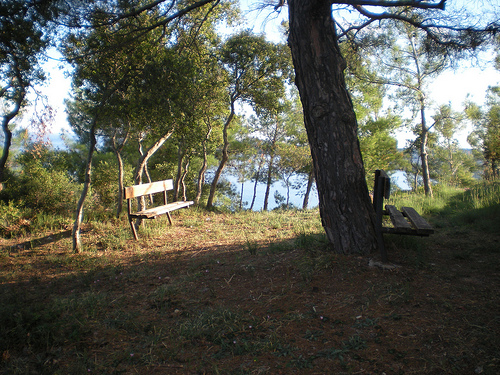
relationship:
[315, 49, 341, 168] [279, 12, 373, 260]
bark on tree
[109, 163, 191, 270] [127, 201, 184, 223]
seat has boards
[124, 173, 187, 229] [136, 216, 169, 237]
bench has legs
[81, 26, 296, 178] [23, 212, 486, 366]
trees have shadows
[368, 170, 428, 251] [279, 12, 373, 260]
bench near tree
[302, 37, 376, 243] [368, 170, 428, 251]
trunk near bench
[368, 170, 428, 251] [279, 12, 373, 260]
bench fastened to tree